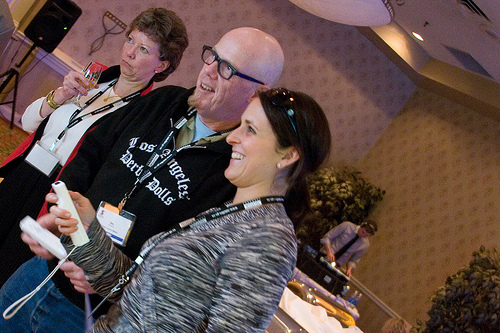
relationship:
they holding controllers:
[7, 22, 341, 330] [18, 174, 93, 264]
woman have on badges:
[93, 87, 332, 333] [75, 189, 166, 255]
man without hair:
[0, 26, 283, 333] [214, 23, 283, 85]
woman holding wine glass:
[0, 7, 190, 288] [79, 44, 103, 111]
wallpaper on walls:
[1, 0, 499, 330] [341, 81, 498, 331]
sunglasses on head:
[272, 78, 307, 138] [225, 82, 325, 201]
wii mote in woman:
[50, 180, 88, 249] [93, 87, 332, 333]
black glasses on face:
[198, 44, 267, 91] [184, 22, 261, 117]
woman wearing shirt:
[105, 82, 347, 328] [151, 200, 291, 331]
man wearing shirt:
[188, 29, 311, 125] [59, 83, 223, 224]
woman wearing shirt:
[37, 21, 140, 141] [8, 40, 150, 167]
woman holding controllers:
[93, 87, 332, 333] [51, 180, 90, 247]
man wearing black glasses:
[0, 26, 283, 333] [201, 45, 265, 86]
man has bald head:
[16, 26, 283, 331] [224, 27, 284, 84]